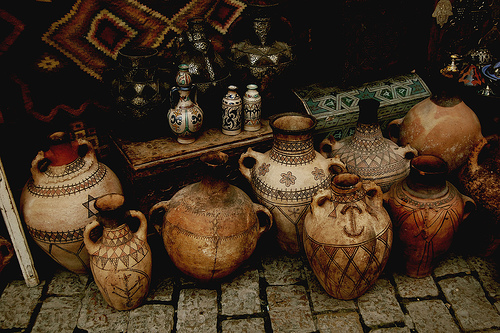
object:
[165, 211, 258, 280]
pottery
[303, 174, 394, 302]
pot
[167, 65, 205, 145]
flask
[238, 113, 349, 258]
jug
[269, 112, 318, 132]
opening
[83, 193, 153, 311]
vases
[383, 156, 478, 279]
vase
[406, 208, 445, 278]
design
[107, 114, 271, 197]
table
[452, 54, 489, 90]
jars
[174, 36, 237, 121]
vases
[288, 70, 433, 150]
box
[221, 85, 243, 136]
ewer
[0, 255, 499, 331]
floor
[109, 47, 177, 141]
pot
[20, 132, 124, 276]
jug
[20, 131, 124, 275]
urn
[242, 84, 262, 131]
jugs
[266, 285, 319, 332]
tiles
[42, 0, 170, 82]
design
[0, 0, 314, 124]
blanket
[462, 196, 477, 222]
handle